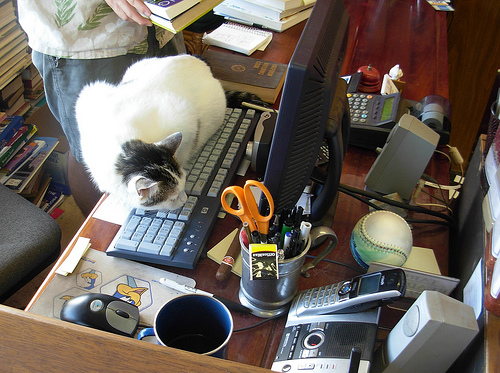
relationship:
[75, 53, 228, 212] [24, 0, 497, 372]
cat on deak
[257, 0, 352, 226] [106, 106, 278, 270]
computer has keyboard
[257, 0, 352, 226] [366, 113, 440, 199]
computer has speaker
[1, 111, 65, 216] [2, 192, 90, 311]
books on floor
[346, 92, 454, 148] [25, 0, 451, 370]
calculator on desk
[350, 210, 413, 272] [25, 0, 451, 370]
ball on desk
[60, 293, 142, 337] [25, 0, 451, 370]
mouse on desk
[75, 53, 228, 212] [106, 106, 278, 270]
cat on a keyboard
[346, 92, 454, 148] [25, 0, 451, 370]
calculator on a desk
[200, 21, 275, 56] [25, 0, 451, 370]
notebook on a desk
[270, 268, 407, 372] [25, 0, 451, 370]
phone on a desk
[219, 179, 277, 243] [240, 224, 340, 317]
scissors in mug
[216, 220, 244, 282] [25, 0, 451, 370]
cigar on a desk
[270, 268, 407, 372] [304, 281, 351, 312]
phone has buttons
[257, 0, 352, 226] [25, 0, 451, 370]
computer on a desk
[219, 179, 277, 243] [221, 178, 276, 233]
scissors have handles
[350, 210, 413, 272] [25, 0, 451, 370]
ball on a desk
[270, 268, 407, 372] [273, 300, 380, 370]
phone on base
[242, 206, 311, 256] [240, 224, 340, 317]
pens in a mug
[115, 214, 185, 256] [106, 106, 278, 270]
number pad on a keyboard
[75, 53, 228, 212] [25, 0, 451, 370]
cat sitting on desk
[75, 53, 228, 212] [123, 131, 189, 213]
cat has head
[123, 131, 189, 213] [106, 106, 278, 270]
head over keyboard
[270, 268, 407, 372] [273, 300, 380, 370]
phone in base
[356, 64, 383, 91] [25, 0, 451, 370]
bell on desk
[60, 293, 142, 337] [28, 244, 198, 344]
mouse on mouse pad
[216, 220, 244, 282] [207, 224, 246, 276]
cigar on pad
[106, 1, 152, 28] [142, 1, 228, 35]
hand holding books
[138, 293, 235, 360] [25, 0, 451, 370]
cup on desk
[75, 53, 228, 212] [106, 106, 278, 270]
cat sitting on keyboard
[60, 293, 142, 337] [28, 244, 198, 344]
mouse sitting on mouse pad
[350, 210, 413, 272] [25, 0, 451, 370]
ball sitting on desk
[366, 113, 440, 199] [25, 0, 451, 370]
speaker sitting on desk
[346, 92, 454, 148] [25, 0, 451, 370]
calculator sitting on desk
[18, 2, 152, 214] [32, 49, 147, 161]
person wearing pants